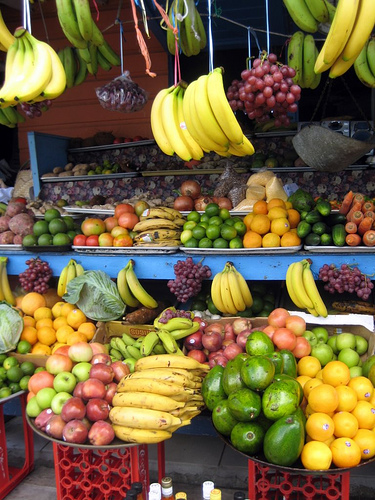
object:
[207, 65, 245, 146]
bananas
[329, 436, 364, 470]
fruit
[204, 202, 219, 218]
fruit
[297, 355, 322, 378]
oranges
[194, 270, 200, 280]
grapes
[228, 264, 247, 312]
bananas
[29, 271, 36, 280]
grapes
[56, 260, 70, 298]
bananas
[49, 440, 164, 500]
crate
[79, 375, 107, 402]
fruit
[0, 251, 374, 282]
wood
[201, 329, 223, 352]
apples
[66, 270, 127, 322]
vegetable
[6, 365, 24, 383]
limes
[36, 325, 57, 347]
oranges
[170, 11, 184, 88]
string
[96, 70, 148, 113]
bags of grapes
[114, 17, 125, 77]
string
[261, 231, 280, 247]
lemons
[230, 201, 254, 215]
tray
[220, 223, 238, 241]
limes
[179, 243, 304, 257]
tray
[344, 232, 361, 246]
carrots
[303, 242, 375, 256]
tray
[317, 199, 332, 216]
cucumber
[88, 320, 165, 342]
box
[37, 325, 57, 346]
lemons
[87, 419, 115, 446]
apples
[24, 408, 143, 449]
tray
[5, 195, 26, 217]
onions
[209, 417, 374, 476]
tray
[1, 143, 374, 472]
collection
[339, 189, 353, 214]
vegetables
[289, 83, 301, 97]
grapes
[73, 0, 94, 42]
plantains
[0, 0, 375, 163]
collection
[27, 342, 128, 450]
assortment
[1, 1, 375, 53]
ceiling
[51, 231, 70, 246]
avocado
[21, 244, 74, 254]
container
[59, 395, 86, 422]
apples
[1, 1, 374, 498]
photo